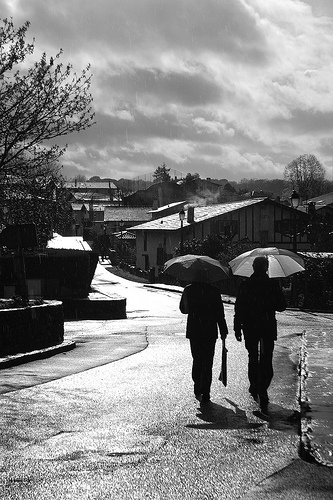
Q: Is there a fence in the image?
A: No, there are no fences.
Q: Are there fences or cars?
A: No, there are no fences or cars.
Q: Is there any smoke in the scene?
A: Yes, there is smoke.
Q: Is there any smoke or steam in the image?
A: Yes, there is smoke.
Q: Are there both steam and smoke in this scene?
A: No, there is smoke but no steam.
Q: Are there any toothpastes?
A: No, there are no toothpastes.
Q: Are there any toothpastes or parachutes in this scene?
A: No, there are no toothpastes or parachutes.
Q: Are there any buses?
A: No, there are no buses.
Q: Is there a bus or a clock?
A: No, there are no buses or clocks.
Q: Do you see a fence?
A: No, there are no fences.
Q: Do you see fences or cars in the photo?
A: No, there are no fences or cars.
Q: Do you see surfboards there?
A: No, there are no surfboards.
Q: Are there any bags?
A: Yes, there is a bag.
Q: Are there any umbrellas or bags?
A: Yes, there is a bag.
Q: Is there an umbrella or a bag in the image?
A: Yes, there is a bag.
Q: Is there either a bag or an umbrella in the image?
A: Yes, there is a bag.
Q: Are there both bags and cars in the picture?
A: No, there is a bag but no cars.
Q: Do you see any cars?
A: No, there are no cars.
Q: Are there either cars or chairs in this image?
A: No, there are no cars or chairs.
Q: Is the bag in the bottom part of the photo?
A: Yes, the bag is in the bottom of the image.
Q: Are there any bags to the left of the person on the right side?
A: Yes, there is a bag to the left of the person.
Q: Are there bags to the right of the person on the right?
A: No, the bag is to the left of the person.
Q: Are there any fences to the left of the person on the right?
A: No, there is a bag to the left of the person.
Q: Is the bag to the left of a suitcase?
A: No, the bag is to the left of the person.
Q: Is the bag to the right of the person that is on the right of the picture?
A: No, the bag is to the left of the person.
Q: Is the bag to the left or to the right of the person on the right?
A: The bag is to the left of the person.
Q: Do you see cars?
A: No, there are no cars.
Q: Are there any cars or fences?
A: No, there are no cars or fences.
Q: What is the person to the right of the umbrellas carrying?
A: The person is carrying a bag.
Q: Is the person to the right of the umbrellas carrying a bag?
A: Yes, the person is carrying a bag.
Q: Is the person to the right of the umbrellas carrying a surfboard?
A: No, the person is carrying a bag.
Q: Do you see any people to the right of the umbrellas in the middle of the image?
A: Yes, there is a person to the right of the umbrellas.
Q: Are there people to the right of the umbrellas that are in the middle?
A: Yes, there is a person to the right of the umbrellas.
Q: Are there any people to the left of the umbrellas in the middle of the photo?
A: No, the person is to the right of the umbrellas.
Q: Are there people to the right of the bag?
A: Yes, there is a person to the right of the bag.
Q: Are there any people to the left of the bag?
A: No, the person is to the right of the bag.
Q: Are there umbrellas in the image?
A: Yes, there is an umbrella.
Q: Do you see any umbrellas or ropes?
A: Yes, there is an umbrella.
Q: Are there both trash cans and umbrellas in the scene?
A: No, there is an umbrella but no trash cans.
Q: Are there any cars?
A: No, there are no cars.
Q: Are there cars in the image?
A: No, there are no cars.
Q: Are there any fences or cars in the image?
A: No, there are no cars or fences.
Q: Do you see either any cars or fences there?
A: No, there are no cars or fences.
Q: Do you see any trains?
A: No, there are no trains.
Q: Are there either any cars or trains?
A: No, there are no trains or cars.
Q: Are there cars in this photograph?
A: No, there are no cars.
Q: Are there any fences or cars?
A: No, there are no cars or fences.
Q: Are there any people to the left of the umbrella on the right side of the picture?
A: Yes, there are people to the left of the umbrella.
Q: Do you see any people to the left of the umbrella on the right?
A: Yes, there are people to the left of the umbrella.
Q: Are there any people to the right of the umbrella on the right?
A: No, the people are to the left of the umbrella.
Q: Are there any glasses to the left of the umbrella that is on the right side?
A: No, there are people to the left of the umbrella.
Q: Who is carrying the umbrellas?
A: The people are carrying the umbrellas.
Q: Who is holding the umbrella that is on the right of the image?
A: The people are holding the umbrella.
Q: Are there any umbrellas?
A: Yes, there are umbrellas.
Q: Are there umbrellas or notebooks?
A: Yes, there are umbrellas.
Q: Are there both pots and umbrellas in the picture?
A: No, there are umbrellas but no pots.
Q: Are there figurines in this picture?
A: No, there are no figurines.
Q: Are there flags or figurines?
A: No, there are no figurines or flags.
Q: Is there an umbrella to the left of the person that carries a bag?
A: Yes, there are umbrellas to the left of the person.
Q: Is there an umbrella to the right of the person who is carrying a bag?
A: No, the umbrellas are to the left of the person.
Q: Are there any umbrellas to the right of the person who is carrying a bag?
A: No, the umbrellas are to the left of the person.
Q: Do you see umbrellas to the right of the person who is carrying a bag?
A: No, the umbrellas are to the left of the person.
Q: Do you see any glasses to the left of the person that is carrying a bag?
A: No, there are umbrellas to the left of the person.